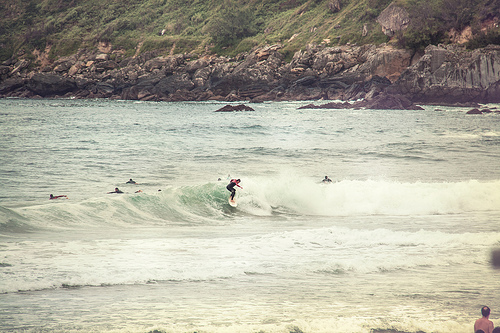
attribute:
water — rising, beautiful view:
[1, 100, 499, 333]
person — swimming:
[126, 179, 137, 185]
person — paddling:
[109, 188, 142, 194]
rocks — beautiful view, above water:
[0, 43, 498, 114]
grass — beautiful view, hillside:
[2, 0, 499, 58]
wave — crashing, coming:
[0, 179, 499, 232]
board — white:
[229, 197, 237, 207]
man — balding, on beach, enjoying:
[474, 307, 494, 333]